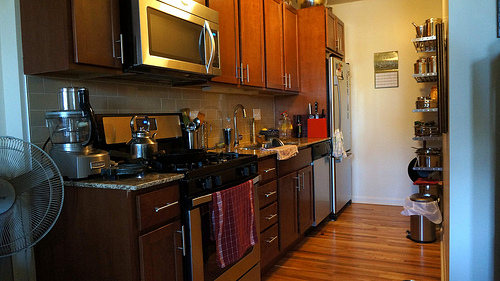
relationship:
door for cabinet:
[239, 2, 264, 84] [206, 0, 300, 93]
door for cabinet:
[239, 2, 264, 84] [279, 162, 314, 254]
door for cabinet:
[262, 0, 284, 89] [206, 0, 300, 93]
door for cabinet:
[262, 0, 284, 89] [279, 162, 314, 254]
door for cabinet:
[281, 0, 301, 89] [206, 0, 300, 93]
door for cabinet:
[281, 0, 301, 89] [279, 162, 314, 254]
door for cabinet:
[206, 0, 239, 84] [206, 0, 300, 93]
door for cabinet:
[206, 0, 239, 84] [279, 162, 314, 254]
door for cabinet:
[296, 165, 314, 235] [206, 0, 300, 93]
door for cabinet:
[296, 165, 314, 235] [279, 162, 314, 254]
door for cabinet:
[275, 172, 300, 257] [206, 0, 300, 93]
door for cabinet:
[275, 172, 300, 257] [279, 162, 314, 254]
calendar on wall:
[373, 50, 399, 88] [345, 1, 444, 201]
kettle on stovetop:
[104, 97, 174, 175] [81, 107, 267, 277]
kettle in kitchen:
[104, 97, 174, 175] [12, 1, 449, 277]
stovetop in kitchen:
[81, 107, 267, 277] [12, 1, 449, 277]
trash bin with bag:
[405, 190, 438, 241] [403, 194, 443, 225]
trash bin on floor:
[405, 190, 438, 241] [248, 198, 445, 278]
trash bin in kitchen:
[405, 190, 438, 241] [12, 1, 449, 277]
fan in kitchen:
[0, 134, 69, 276] [2, 0, 496, 276]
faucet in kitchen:
[226, 101, 277, 151] [12, 1, 449, 277]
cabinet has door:
[17, 0, 134, 80] [67, 0, 126, 70]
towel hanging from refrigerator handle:
[330, 127, 349, 159] [335, 81, 342, 123]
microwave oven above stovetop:
[127, 1, 238, 81] [129, 142, 254, 172]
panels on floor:
[311, 219, 415, 266] [340, 207, 388, 279]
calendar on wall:
[373, 50, 399, 86] [372, 113, 377, 127]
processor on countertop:
[44, 84, 131, 184] [35, 170, 186, 190]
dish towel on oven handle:
[207, 187, 259, 262] [184, 181, 256, 206]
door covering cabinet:
[206, 0, 239, 84] [206, 0, 266, 89]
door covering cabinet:
[239, 2, 264, 84] [238, 0, 265, 89]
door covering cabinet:
[262, 0, 284, 89] [263, 0, 300, 94]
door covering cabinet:
[281, 0, 301, 89] [281, 2, 302, 90]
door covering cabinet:
[324, 9, 336, 51] [323, 9, 345, 56]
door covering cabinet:
[206, 0, 239, 84] [216, 2, 299, 91]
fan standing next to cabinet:
[0, 134, 69, 276] [36, 180, 187, 276]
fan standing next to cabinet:
[0, 134, 69, 276] [208, 144, 280, 270]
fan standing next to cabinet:
[0, 134, 69, 276] [279, 166, 315, 255]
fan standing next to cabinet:
[0, 134, 69, 276] [17, 0, 134, 80]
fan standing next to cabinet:
[0, 134, 69, 276] [206, 0, 241, 88]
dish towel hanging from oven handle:
[209, 178, 257, 267] [186, 171, 264, 207]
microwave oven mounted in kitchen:
[102, 10, 251, 92] [42, 15, 404, 246]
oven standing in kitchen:
[96, 112, 273, 279] [12, 1, 449, 277]